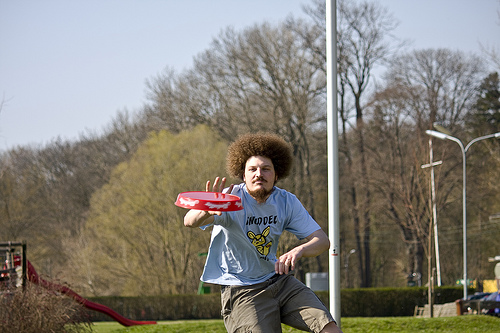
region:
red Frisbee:
[180, 176, 247, 214]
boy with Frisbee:
[182, 116, 294, 323]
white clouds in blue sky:
[11, 12, 69, 64]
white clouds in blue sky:
[38, 72, 59, 116]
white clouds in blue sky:
[30, 58, 75, 108]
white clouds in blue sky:
[77, 56, 109, 81]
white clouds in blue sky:
[400, 23, 447, 57]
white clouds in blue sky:
[97, 11, 159, 45]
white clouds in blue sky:
[85, 35, 133, 70]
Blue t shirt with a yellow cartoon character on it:
[200, 183, 323, 288]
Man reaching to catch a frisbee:
[182, 129, 342, 331]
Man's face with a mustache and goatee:
[245, 155, 277, 202]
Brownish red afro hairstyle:
[224, 133, 293, 181]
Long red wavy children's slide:
[0, 251, 157, 327]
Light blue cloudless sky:
[0, 0, 498, 151]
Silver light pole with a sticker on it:
[325, 0, 341, 332]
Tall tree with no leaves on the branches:
[284, 0, 404, 287]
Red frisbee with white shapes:
[173, 189, 244, 213]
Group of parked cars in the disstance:
[454, 289, 498, 316]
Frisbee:
[178, 185, 244, 212]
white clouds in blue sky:
[12, 47, 52, 87]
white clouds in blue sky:
[43, 35, 93, 80]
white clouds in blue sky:
[120, 34, 150, 49]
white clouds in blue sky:
[48, 96, 99, 133]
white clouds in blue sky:
[454, 32, 492, 51]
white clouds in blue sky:
[17, 65, 60, 125]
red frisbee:
[174, 178, 231, 215]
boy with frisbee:
[179, 123, 305, 306]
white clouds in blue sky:
[110, 13, 143, 55]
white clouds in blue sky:
[41, 56, 77, 93]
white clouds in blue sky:
[45, 3, 95, 50]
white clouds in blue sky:
[72, 75, 112, 122]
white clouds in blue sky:
[7, 10, 39, 51]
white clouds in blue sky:
[94, 15, 135, 61]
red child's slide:
[3, 225, 162, 331]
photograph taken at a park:
[32, 25, 471, 315]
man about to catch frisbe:
[167, 121, 344, 326]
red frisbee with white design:
[158, 183, 251, 230]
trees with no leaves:
[47, 28, 452, 291]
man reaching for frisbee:
[160, 127, 362, 330]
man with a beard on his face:
[210, 127, 307, 213]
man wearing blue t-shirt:
[185, 136, 329, 288]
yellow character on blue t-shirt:
[245, 221, 287, 271]